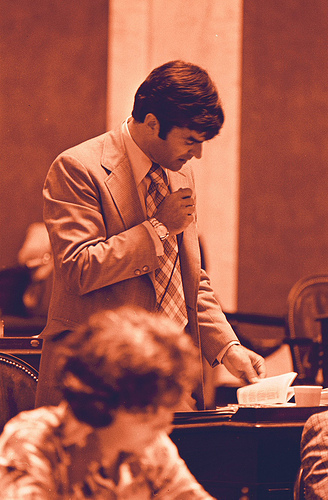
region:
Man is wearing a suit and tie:
[34, 57, 272, 416]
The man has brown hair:
[119, 52, 224, 176]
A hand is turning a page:
[171, 342, 299, 421]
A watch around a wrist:
[144, 212, 173, 243]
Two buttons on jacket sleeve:
[127, 257, 152, 279]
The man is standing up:
[29, 52, 271, 419]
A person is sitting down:
[0, 301, 218, 497]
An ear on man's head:
[139, 110, 163, 139]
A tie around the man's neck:
[141, 158, 191, 335]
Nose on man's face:
[186, 137, 205, 163]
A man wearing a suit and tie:
[11, 34, 312, 357]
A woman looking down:
[10, 298, 242, 499]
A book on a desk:
[206, 368, 301, 415]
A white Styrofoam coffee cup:
[289, 382, 326, 410]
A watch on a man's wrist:
[139, 208, 180, 250]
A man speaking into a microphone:
[40, 45, 273, 286]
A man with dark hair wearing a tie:
[20, 61, 266, 306]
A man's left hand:
[210, 329, 276, 386]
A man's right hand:
[135, 182, 211, 252]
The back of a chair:
[0, 336, 56, 434]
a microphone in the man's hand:
[159, 180, 197, 234]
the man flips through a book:
[234, 368, 303, 404]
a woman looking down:
[8, 305, 205, 497]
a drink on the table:
[290, 383, 322, 408]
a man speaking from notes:
[30, 61, 265, 409]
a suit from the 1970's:
[33, 117, 238, 400]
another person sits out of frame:
[296, 409, 325, 498]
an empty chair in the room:
[282, 268, 326, 385]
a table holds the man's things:
[159, 396, 327, 458]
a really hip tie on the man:
[142, 164, 188, 331]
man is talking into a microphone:
[169, 183, 191, 227]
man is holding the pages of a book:
[226, 371, 292, 411]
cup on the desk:
[288, 382, 320, 408]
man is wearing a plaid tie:
[143, 173, 199, 342]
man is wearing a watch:
[146, 214, 173, 246]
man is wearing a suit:
[61, 130, 227, 285]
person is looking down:
[20, 338, 184, 490]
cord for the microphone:
[164, 228, 179, 310]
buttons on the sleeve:
[130, 258, 155, 279]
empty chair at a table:
[284, 257, 324, 359]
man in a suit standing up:
[37, 60, 265, 407]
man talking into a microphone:
[39, 58, 263, 408]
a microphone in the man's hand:
[160, 187, 195, 313]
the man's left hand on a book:
[224, 343, 296, 405]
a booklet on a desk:
[223, 375, 297, 412]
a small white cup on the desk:
[294, 384, 319, 407]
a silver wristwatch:
[147, 216, 167, 240]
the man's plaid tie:
[145, 166, 187, 330]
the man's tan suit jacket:
[36, 130, 241, 409]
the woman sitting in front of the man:
[0, 321, 215, 495]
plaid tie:
[145, 162, 188, 334]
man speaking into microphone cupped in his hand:
[32, 58, 327, 403]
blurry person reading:
[0, 303, 221, 498]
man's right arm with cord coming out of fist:
[41, 156, 197, 297]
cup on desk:
[292, 384, 321, 408]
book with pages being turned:
[215, 371, 299, 415]